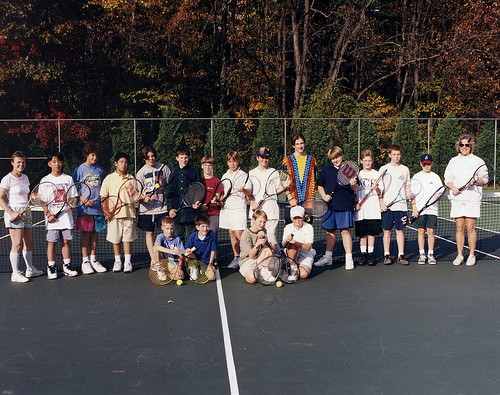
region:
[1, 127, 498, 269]
THE KIDS ARE STANDING TOGETHER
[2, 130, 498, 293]
THE KIDS ARE HOLDING RACKETS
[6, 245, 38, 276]
THE WOMAN IS WEARING WHITE SOCKS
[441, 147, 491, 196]
THE WOMAN IS WEARING A WHITE SHIRT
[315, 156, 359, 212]
THE BOY IS WEARING A BLUE SHIRT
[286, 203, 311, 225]
THE BOY IS WEARING A WHITE HAT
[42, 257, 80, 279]
THE KID HAS BLACK LACES IN HIS SHOES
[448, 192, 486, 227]
THE WOMAN IS WEARING A WHITE SKIRT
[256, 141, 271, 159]
THE KID IS WEARING A BLUE HAT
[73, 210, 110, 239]
THE KID IS WEARING TWO TONED SHORTS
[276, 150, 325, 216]
a very colorful shirt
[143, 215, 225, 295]
a pair of young boys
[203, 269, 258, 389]
a white stripe on the floor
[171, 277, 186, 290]
a yellow tennis ball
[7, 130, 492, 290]
a group of tennis players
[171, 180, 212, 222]
a true blue racket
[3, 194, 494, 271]
a black net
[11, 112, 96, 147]
a tree with autumn foliage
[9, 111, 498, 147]
a chain link metal fence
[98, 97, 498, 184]
a row of evergreen trees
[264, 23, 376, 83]
branches behind the fence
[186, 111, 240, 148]
fence behind the people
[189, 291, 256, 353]
white line on the court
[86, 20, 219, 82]
many trees behind the fence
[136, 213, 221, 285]
kids on the court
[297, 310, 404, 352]
blue court below the people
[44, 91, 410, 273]
people with rackets in hands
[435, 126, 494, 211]
lady with sunglasses on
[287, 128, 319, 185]
person wearing many colors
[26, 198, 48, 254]
tennis net behind people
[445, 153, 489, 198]
the woman is wearing a white sweater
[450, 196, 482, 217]
the woman is wearing a white skirt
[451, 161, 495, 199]
the woman is holding a tennis racket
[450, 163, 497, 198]
the racket is black in color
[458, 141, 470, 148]
the woman is wearing sunglasses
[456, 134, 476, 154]
the woman's hair is light brown in color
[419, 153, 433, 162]
the boy is wearing a baseball hat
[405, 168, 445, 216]
the boy is wearing a white shirt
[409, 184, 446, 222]
the boy is wearing a tennis racket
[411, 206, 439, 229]
the boy is wearing black shorts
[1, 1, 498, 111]
tall trees with colorful leaves in the background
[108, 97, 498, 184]
a row of evergreen trees just behind the fence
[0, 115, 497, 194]
a metal fence behind the people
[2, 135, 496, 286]
a row of people standing on a tennis court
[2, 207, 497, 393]
the tennis court is gray with a white stripe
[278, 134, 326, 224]
the person in the tie-dyed shirt is holding a tennis racket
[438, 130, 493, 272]
the woman on the right is holding a tennis racket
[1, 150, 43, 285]
the woman on the left has short hair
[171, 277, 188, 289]
a yellow tennis ball lies on the court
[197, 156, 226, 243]
the kid in a red shirt holds a tennis racket